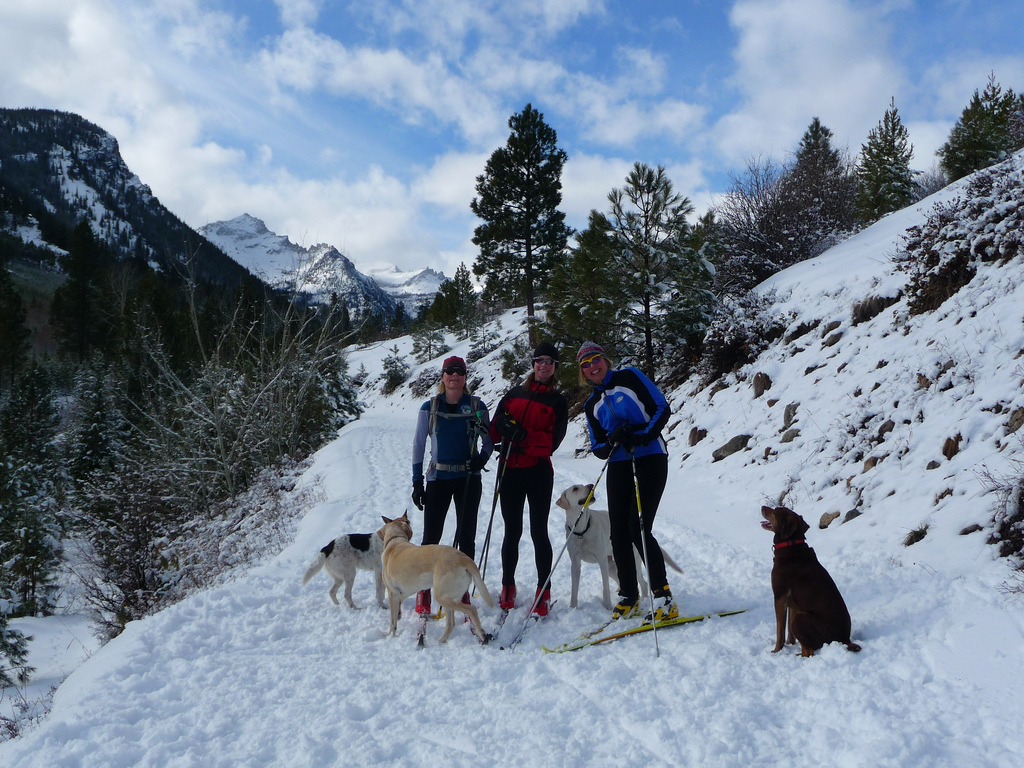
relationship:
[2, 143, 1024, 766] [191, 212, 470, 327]
snow covering mountains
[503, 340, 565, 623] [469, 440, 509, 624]
skier holding poles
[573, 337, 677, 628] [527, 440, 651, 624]
person holding poles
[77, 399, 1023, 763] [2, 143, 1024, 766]
footprints on snow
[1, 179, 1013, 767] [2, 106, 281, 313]
snow on mountain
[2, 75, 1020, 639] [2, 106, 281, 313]
trees on mountain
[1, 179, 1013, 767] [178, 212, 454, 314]
snow on mountain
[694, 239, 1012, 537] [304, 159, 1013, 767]
rocks on hills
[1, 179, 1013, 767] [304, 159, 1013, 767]
snow on hills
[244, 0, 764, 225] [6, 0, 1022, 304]
cloud in sky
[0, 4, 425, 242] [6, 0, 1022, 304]
cloud in sky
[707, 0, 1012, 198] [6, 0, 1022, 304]
cloud in sky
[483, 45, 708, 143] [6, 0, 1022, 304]
cloud in sky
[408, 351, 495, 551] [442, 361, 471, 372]
person wears sunglasses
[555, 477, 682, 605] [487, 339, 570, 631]
dog near people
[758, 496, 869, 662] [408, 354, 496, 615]
dog near person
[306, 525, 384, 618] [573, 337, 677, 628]
dog near person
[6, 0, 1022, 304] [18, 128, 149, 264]
sky above snow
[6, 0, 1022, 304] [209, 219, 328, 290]
sky above snow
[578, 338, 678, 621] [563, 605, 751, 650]
person on ski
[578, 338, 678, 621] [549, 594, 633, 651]
person on ski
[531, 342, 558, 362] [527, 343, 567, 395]
hat on head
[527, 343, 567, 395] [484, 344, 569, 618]
head of skier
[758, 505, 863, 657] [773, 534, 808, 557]
dog wearing collar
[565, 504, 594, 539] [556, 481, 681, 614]
neck of dog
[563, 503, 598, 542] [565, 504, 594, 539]
collar around neck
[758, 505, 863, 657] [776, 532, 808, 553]
dog wearing collar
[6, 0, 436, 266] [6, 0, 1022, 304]
cloud in sky